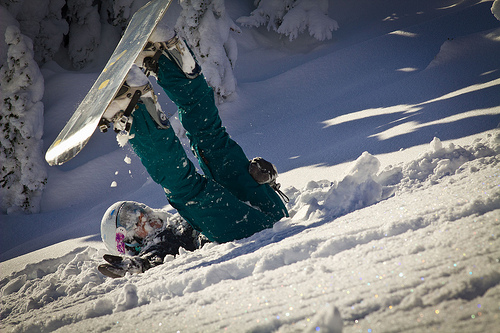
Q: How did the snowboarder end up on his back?
A: He fell.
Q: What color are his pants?
A: Green.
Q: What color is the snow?
A: White.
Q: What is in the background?
A: Pine trees.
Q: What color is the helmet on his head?
A: White.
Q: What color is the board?
A: Black.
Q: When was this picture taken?
A: During the day time.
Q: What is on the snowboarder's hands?
A: Mittens.